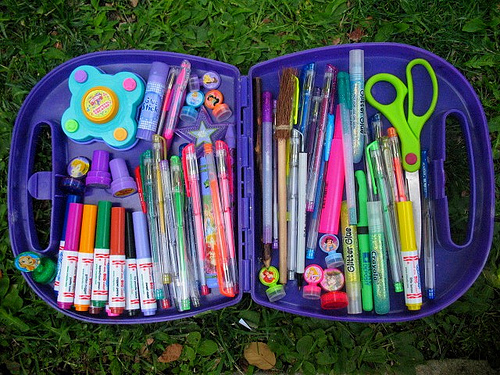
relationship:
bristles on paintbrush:
[269, 64, 303, 134] [278, 70, 323, 132]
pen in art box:
[333, 72, 358, 224] [6, 42, 491, 317]